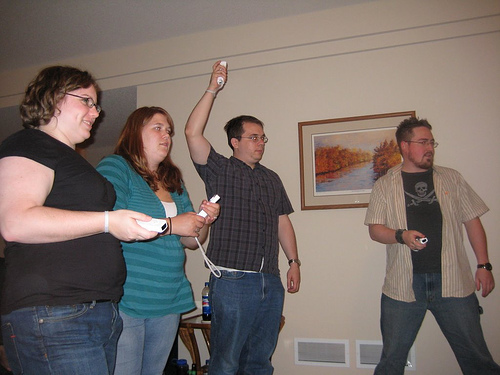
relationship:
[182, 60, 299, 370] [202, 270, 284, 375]
man wearing jeans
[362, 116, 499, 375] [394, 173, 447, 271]
man wearing shirt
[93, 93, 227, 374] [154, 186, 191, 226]
woman wearing shirt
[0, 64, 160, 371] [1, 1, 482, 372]
person playing in room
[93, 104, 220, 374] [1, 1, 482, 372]
woman playing in room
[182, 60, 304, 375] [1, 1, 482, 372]
man playing in room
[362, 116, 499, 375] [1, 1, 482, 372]
man playing in room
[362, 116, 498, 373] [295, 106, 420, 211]
man standing in front of picture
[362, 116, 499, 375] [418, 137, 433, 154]
man wearing glasses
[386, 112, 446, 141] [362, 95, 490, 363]
short hair belonging to man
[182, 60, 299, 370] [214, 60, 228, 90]
man holding up game command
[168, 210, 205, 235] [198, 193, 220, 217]
hand holding command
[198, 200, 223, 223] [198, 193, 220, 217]
hand holding command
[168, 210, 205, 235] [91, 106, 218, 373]
hand belonging to woman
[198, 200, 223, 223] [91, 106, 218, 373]
hand belonging to woman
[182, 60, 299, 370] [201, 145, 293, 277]
man wearing shirt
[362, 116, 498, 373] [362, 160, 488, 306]
man wearing shirt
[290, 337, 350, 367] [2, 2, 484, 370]
vent built into wall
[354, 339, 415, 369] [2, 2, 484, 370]
vent built into wall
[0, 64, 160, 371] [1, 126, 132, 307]
person wearing shirt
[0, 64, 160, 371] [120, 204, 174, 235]
person holding controller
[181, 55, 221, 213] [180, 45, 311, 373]
arm in air on man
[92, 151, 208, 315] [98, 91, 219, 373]
shirt on woman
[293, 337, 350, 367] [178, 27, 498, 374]
vent on wall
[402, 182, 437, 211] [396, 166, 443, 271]
skull on shirt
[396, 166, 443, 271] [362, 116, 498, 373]
shirt on man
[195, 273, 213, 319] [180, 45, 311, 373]
bottle behind man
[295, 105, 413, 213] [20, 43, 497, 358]
painting on wall